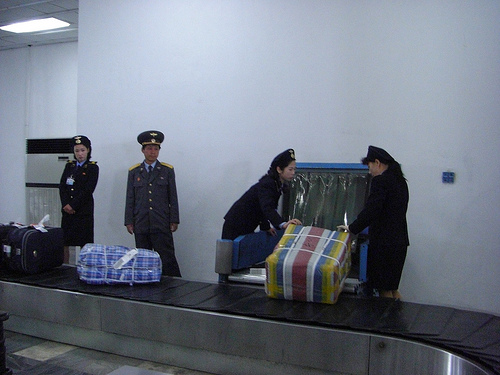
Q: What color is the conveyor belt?
A: Black.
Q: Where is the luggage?
A: On the conveyor belt.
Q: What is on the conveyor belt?
A: Luggage.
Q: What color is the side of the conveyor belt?
A: Silver.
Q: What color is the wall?
A: White.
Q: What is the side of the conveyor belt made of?
A: Metal.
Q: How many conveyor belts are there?
A: One.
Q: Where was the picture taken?
A: Terminal.